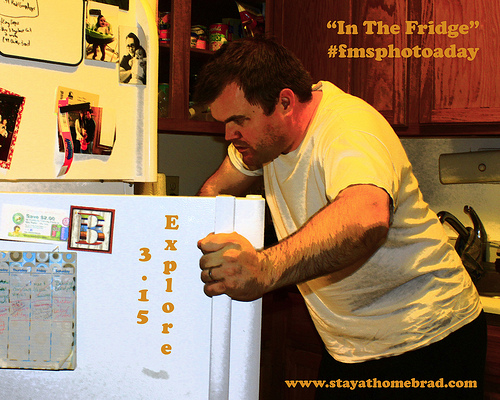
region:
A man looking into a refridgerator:
[169, 31, 491, 373]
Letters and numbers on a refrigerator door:
[125, 205, 194, 361]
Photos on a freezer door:
[57, 1, 154, 165]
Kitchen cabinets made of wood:
[255, 0, 495, 133]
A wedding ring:
[195, 226, 261, 304]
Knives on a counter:
[430, 195, 495, 295]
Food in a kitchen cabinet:
[145, 0, 276, 90]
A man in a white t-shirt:
[202, 15, 487, 365]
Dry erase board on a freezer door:
[0, 0, 91, 68]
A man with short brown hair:
[193, 30, 320, 178]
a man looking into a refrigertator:
[26, 5, 356, 282]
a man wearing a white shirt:
[220, 45, 410, 316]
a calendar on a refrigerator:
[0, 237, 95, 362]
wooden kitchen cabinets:
[294, 18, 447, 119]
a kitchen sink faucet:
[424, 199, 485, 279]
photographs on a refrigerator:
[55, 10, 162, 94]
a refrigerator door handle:
[186, 185, 253, 389]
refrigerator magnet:
[47, 212, 124, 252]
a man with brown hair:
[186, 32, 369, 145]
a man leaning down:
[184, 32, 369, 212]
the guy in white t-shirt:
[139, 87, 499, 282]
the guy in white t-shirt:
[185, 48, 366, 265]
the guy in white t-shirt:
[173, 90, 381, 365]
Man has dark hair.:
[218, 53, 327, 137]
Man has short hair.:
[207, 72, 342, 123]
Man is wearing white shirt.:
[324, 156, 430, 284]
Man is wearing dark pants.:
[364, 349, 467, 397]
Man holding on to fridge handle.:
[196, 183, 272, 345]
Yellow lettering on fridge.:
[137, 200, 179, 390]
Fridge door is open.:
[113, 162, 231, 263]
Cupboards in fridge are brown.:
[401, 73, 478, 153]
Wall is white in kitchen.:
[416, 165, 473, 219]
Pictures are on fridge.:
[53, 92, 172, 195]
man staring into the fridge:
[182, 45, 487, 397]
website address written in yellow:
[285, 371, 482, 394]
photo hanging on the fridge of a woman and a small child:
[117, 27, 149, 86]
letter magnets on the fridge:
[158, 213, 185, 365]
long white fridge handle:
[207, 197, 235, 399]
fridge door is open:
[1, 184, 283, 399]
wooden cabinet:
[411, 1, 498, 123]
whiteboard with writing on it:
[2, 0, 86, 67]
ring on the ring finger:
[206, 266, 213, 281]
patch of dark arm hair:
[274, 248, 294, 268]